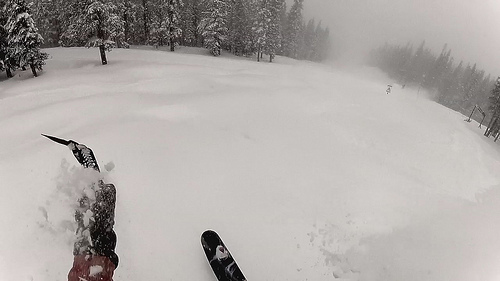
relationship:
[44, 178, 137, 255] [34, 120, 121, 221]
glove holding pole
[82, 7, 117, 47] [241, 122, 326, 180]
tree in snow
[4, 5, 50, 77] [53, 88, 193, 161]
tree in snow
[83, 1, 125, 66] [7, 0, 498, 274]
tree in snow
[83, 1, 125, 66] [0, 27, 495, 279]
tree in snow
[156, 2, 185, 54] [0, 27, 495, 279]
tree in snow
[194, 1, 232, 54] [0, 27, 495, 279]
tree in snow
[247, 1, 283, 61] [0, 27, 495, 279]
tree in snow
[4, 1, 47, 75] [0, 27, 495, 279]
tree in snow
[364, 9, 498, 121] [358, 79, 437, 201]
trees in snow